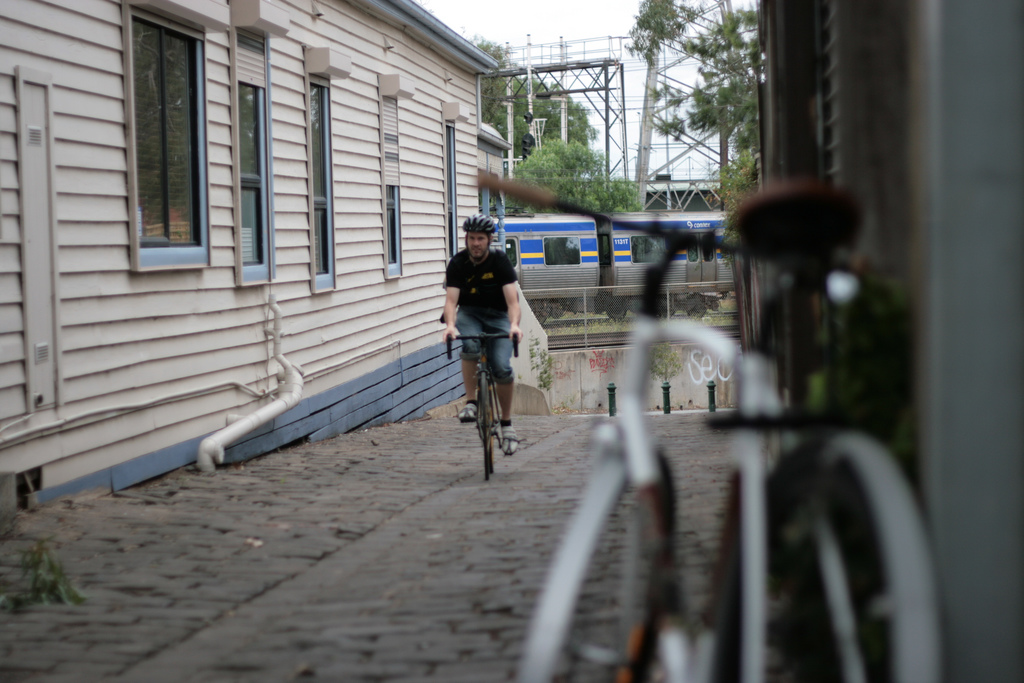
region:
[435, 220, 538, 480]
Man riding a bike between buildings.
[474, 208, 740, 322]
Sliver and blue train car behind buildings.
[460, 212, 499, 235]
Helmet on a man riding a bike.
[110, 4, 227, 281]
Closest window on the left building.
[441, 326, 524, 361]
Handlebars with two hands on them.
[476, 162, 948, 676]
White blurry bike closest to the camera.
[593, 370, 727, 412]
Three short black poles in the ground.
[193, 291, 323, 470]
White pipe on the side of a building.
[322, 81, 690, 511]
man on a bike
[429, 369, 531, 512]
front tire of bike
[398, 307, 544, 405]
handlebars on the bike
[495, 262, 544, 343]
arm of the man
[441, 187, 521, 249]
helmet on the person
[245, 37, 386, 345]
window next to man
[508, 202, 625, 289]
window on the train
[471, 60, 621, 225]
trees near the train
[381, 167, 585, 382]
man in a black shirt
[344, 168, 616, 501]
man riding with a helmet on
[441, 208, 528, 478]
man riding a bicycle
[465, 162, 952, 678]
bicycle leaning against a building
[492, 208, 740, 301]
blue, yellow and silver train in background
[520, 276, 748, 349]
fence to keep off the tracks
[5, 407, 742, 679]
red brick walk between buildings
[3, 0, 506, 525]
white building with blue trim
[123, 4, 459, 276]
windows in the white house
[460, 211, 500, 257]
helmet on man's head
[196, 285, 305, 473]
water spout on side of house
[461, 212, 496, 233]
The helmet on the man's head riding the bike.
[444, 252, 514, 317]
The black shirt the man is wearing.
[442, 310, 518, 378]
The shorts the man is wearing on the bike.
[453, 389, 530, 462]
The sneakers the man is wearing on the bike.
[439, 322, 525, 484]
The bike the man is riding.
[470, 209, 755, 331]
The train in the distance behind the man on the bike.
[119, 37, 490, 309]
The windows on the side of the house.